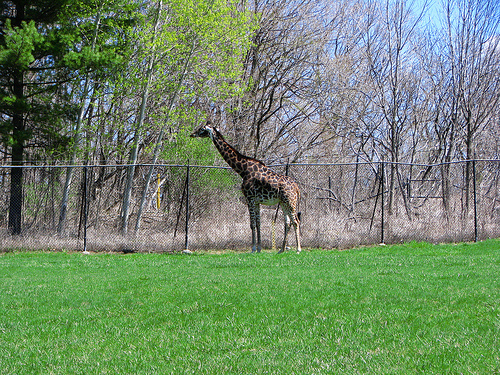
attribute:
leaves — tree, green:
[5, 6, 249, 71]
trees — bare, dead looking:
[334, 35, 444, 212]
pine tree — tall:
[1, 0, 143, 237]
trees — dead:
[363, 80, 425, 158]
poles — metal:
[170, 158, 196, 249]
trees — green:
[21, 8, 216, 235]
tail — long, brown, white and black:
[295, 186, 302, 221]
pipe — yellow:
[146, 171, 172, 218]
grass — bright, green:
[2, 251, 499, 371]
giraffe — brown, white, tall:
[185, 118, 304, 255]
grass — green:
[383, 235, 443, 284]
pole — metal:
[0, 158, 497, 168]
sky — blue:
[323, 2, 498, 81]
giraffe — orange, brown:
[193, 120, 304, 249]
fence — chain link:
[6, 162, 217, 249]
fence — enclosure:
[337, 163, 479, 239]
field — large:
[0, 235, 498, 373]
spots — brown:
[214, 143, 304, 253]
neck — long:
[214, 136, 251, 176]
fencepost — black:
[78, 157, 88, 256]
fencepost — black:
[374, 154, 387, 243]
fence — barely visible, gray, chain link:
[6, 156, 481, 250]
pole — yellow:
[147, 169, 166, 219]